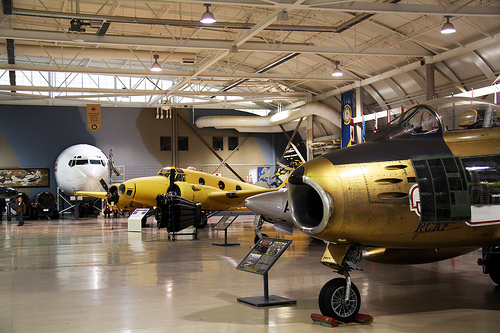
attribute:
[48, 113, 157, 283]
airplane — white 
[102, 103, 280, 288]
airplane — gold 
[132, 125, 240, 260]
airplane — gold 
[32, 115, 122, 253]
airplane — white 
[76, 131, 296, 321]
plane — black , gold 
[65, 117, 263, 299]
airplane — Yellow 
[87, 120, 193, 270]
plane — golden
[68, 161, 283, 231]
plane — yellow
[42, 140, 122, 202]
plane — white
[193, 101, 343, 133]
tubes — white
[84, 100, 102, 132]
banner — yellow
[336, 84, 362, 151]
banner — blue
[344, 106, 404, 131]
flags — rows of, hung up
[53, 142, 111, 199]
body — white airplane, without wings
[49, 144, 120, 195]
body — white airplane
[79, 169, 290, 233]
airplane — small, yellow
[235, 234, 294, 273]
sign — black, frame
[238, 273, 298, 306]
base — black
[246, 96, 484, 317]
airplane — black, gold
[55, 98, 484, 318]
airplanes — four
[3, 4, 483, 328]
hangar — large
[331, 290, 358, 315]
rim — chrome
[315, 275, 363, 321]
wheel — black, rubber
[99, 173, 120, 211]
propeller — black, airplane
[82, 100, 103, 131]
banner — yellow, hanging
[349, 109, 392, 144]
flags — four, hanging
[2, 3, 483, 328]
hanger — museum, airplane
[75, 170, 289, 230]
plane — yellow, personal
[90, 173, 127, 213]
propeller — black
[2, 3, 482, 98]
railing — ceiling, white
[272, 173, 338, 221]
trim — silver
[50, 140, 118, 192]
jet — front of, white, pilot 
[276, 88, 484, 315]
plane — personal, gold, model , old , 20th century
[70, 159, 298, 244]
airplane — large, yellow